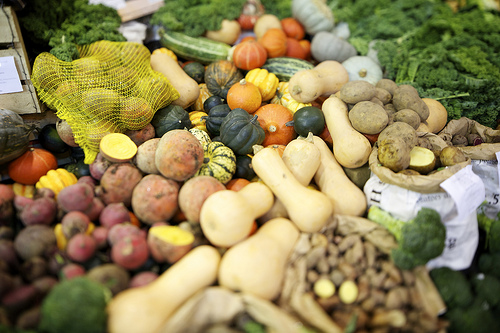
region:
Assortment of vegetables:
[2, 1, 497, 324]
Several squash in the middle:
[207, 93, 369, 325]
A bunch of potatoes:
[17, 171, 153, 282]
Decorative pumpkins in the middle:
[178, 100, 287, 196]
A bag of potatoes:
[24, 29, 187, 164]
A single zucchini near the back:
[155, 18, 241, 66]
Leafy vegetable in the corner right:
[395, 0, 495, 136]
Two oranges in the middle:
[221, 75, 310, 156]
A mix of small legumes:
[296, 231, 428, 331]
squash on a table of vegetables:
[244, 138, 334, 232]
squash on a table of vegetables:
[194, 178, 277, 245]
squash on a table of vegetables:
[222, 218, 299, 303]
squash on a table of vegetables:
[88, 242, 219, 328]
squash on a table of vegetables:
[306, 128, 367, 216]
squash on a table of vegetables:
[256, 131, 318, 221]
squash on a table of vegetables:
[323, 94, 370, 170]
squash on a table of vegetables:
[289, 51, 349, 109]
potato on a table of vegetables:
[376, 116, 419, 177]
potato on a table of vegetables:
[347, 97, 390, 135]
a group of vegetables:
[178, 128, 418, 326]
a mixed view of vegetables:
[27, 12, 460, 332]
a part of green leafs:
[33, 259, 115, 329]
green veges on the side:
[376, 14, 497, 87]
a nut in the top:
[5, 35, 190, 160]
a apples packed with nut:
[15, 41, 175, 129]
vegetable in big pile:
[155, 131, 202, 178]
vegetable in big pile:
[175, 180, 216, 220]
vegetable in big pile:
[128, 172, 174, 234]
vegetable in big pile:
[96, 161, 138, 202]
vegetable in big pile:
[98, 197, 128, 227]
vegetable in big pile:
[106, 223, 146, 240]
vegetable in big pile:
[53, 178, 93, 212]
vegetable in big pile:
[62, 234, 97, 259]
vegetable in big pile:
[17, 195, 52, 225]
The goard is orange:
[219, 24, 276, 74]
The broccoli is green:
[360, 205, 447, 272]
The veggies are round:
[49, 179, 159, 281]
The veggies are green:
[380, 13, 482, 123]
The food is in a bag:
[39, 47, 167, 130]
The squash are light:
[184, 150, 401, 317]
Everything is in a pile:
[159, 7, 413, 191]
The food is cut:
[79, 128, 143, 165]